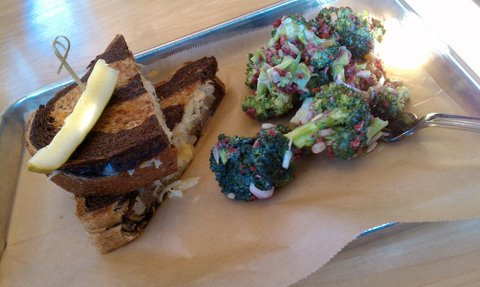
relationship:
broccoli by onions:
[251, 54, 352, 173] [269, 116, 316, 172]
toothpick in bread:
[48, 34, 100, 98] [118, 81, 182, 171]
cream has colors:
[380, 18, 462, 101] [402, 36, 473, 104]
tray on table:
[168, 19, 301, 44] [87, 6, 203, 32]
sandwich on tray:
[25, 44, 199, 253] [168, 19, 301, 44]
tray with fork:
[168, 19, 301, 44] [358, 113, 479, 141]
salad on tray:
[251, 44, 411, 161] [168, 19, 301, 44]